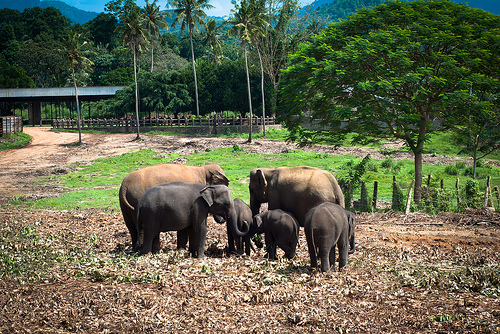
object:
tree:
[275, 0, 498, 208]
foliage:
[51, 216, 84, 239]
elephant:
[245, 206, 303, 260]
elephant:
[226, 197, 257, 255]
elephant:
[302, 201, 359, 273]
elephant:
[245, 165, 346, 226]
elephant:
[132, 182, 249, 258]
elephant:
[118, 162, 230, 249]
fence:
[54, 116, 279, 129]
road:
[1, 121, 90, 166]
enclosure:
[0, 128, 499, 334]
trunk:
[226, 206, 251, 238]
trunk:
[248, 190, 261, 218]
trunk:
[347, 230, 357, 255]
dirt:
[1, 126, 137, 166]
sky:
[1, 0, 498, 20]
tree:
[38, 31, 95, 146]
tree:
[113, 0, 168, 142]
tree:
[164, 0, 215, 121]